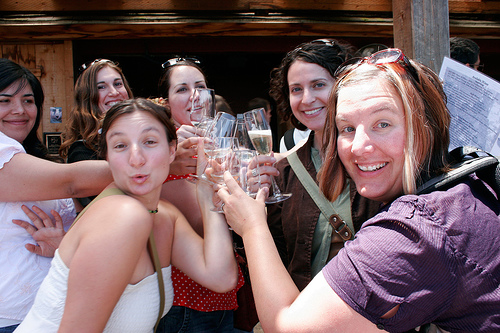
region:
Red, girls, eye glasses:
[333, 45, 430, 83]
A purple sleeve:
[323, 196, 460, 331]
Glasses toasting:
[183, 86, 298, 222]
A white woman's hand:
[8, 201, 68, 261]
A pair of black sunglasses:
[158, 55, 208, 67]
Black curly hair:
[266, 38, 347, 123]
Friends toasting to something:
[0, 25, 498, 330]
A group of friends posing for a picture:
[0, 26, 499, 331]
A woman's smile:
[351, 158, 394, 179]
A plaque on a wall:
[41, 131, 66, 161]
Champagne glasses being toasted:
[184, 87, 287, 207]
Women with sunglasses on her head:
[220, 63, 460, 330]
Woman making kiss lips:
[10, 96, 238, 328]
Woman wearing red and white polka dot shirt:
[145, 57, 247, 329]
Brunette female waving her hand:
[0, 56, 100, 331]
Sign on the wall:
[42, 130, 66, 160]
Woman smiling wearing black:
[65, 56, 142, 202]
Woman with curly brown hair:
[270, 37, 376, 260]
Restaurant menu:
[432, 50, 498, 158]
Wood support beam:
[387, 1, 459, 81]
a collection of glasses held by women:
[184, 88, 289, 205]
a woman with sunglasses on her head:
[323, 46, 413, 198]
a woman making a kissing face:
[102, 105, 172, 195]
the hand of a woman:
[14, 206, 66, 256]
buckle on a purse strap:
[327, 214, 350, 240]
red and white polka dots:
[170, 273, 242, 310]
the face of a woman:
[285, 57, 335, 129]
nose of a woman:
[301, 87, 315, 105]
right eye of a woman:
[176, 82, 186, 95]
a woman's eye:
[371, 119, 392, 130]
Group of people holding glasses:
[7, 37, 492, 317]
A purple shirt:
[319, 184, 497, 326]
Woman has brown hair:
[88, 94, 185, 191]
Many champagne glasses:
[179, 91, 300, 226]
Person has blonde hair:
[310, 50, 463, 197]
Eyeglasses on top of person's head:
[325, 41, 421, 113]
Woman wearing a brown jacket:
[259, 29, 383, 269]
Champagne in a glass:
[235, 98, 298, 208]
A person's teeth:
[345, 150, 400, 185]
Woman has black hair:
[0, 45, 59, 165]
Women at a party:
[3, 17, 498, 332]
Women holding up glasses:
[3, 12, 496, 332]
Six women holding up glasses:
[0, 40, 496, 327]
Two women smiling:
[224, 46, 499, 331]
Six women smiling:
[0, 34, 497, 329]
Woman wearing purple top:
[220, 43, 495, 327]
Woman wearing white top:
[20, 81, 237, 329]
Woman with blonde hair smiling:
[77, 55, 140, 143]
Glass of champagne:
[245, 107, 288, 207]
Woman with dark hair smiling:
[268, 36, 370, 277]